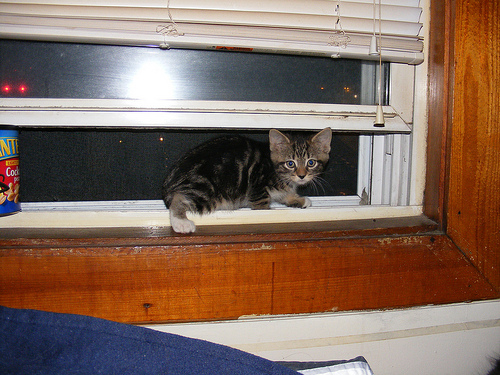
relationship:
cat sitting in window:
[162, 127, 333, 234] [0, 39, 429, 239]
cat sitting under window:
[172, 111, 379, 251] [0, 39, 429, 239]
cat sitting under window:
[162, 127, 333, 234] [0, 39, 429, 239]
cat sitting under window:
[162, 127, 333, 234] [2, 3, 391, 107]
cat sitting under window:
[162, 127, 333, 234] [3, 0, 438, 245]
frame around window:
[8, 12, 499, 337] [0, 39, 429, 239]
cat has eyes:
[162, 127, 333, 234] [259, 136, 341, 164]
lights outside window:
[0, 83, 30, 94] [11, 24, 434, 217]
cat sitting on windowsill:
[162, 127, 333, 234] [3, 203, 424, 227]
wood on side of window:
[1, 1, 498, 323] [1, 39, 416, 134]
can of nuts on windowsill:
[0, 131, 23, 214] [0, 203, 438, 235]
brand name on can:
[0, 137, 22, 159] [0, 122, 25, 218]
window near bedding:
[0, 39, 429, 239] [3, 297, 378, 373]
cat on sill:
[162, 127, 333, 234] [2, 201, 455, 246]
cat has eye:
[162, 127, 333, 234] [284, 159, 302, 172]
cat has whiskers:
[162, 127, 333, 234] [273, 159, 331, 189]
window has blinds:
[1, 39, 416, 134] [0, 0, 424, 65]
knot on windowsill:
[135, 295, 157, 310] [1, 1, 438, 243]